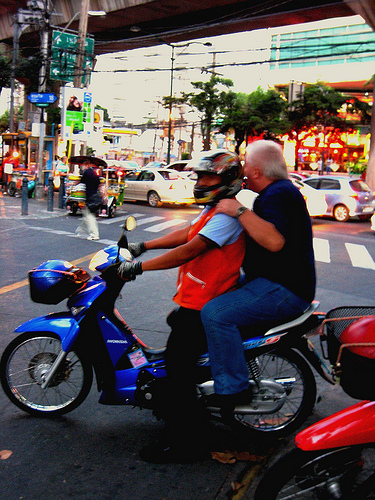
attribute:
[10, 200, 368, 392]
bike — red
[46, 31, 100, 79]
traffic sign — green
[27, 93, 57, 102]
traffic sign — blue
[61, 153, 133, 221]
food cart — being pushed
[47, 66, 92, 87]
street sign — green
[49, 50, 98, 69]
street sign — green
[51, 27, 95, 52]
street sign — green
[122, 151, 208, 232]
sedan — white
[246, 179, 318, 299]
tshirt — black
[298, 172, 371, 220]
hatchback — silver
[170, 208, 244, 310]
vest — red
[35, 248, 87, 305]
basket — black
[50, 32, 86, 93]
sign — green, road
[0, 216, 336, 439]
motorcycle — blue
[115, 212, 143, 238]
mirror — rearview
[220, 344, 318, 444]
tire — rear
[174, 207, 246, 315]
vest — red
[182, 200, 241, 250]
shirt — blue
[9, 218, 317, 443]
motor bike — blue